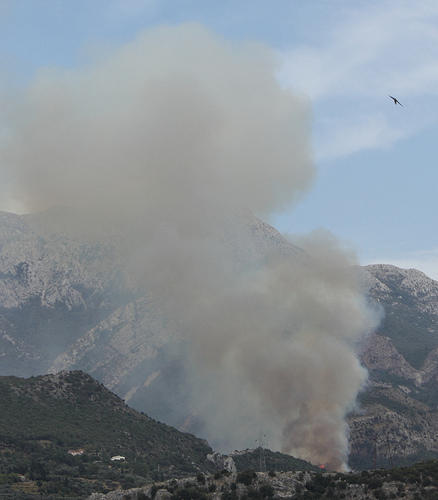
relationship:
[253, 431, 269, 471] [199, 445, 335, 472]
electricaltower on mountain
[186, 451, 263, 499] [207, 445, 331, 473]
tree on mountain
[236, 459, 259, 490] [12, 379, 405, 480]
tree on mountain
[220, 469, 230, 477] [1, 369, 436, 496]
tree on mountain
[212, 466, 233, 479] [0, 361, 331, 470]
tree in mountain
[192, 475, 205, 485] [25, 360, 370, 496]
tree in mountain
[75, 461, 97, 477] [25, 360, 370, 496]
tree in mountain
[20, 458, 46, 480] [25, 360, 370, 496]
tree in mountain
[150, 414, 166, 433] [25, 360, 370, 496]
tree in mountain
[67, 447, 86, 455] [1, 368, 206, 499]
building on mountain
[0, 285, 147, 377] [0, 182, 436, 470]
patch on mountain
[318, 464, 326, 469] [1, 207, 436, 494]
flames in mountain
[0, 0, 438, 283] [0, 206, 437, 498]
cloud above mountains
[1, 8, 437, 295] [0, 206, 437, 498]
sky above mountains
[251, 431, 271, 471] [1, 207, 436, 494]
electricaltower on mountain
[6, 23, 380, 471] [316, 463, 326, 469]
smoke from flames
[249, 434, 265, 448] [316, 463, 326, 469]
ash from flames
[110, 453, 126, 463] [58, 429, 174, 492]
rock on ground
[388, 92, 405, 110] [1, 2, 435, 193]
bird in sky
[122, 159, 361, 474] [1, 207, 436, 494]
smoke in mountain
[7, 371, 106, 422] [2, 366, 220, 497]
hill covered in vegetation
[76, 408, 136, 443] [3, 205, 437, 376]
plants covering mountain top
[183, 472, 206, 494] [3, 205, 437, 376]
trees covering mountain top